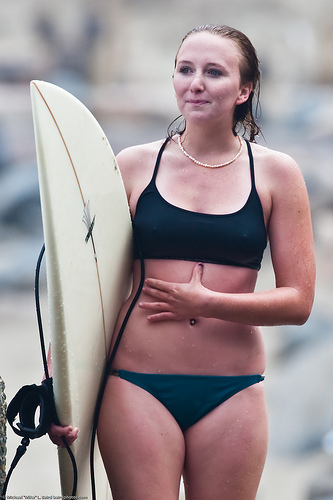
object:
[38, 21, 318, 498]
woman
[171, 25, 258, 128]
head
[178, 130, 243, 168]
necklace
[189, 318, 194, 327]
bellybutton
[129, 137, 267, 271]
bathing suit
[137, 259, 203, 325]
hand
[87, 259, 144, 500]
leash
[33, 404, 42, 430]
velcro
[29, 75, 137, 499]
surfboard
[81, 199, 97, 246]
logo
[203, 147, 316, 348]
arm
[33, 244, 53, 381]
strap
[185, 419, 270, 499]
leg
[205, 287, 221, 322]
wrist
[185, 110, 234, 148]
neck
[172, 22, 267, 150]
hair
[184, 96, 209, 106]
lips